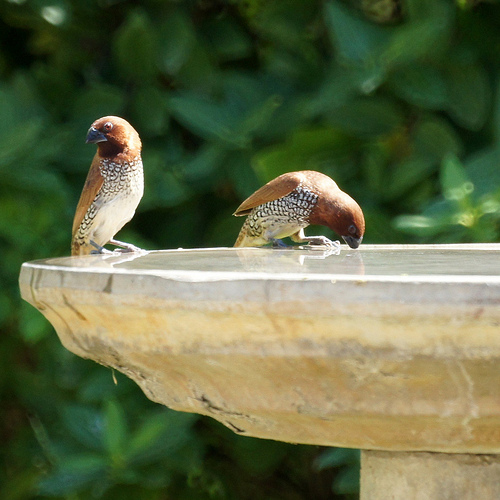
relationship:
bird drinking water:
[226, 168, 368, 253] [44, 244, 499, 278]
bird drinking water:
[70, 112, 144, 256] [44, 244, 499, 278]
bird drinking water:
[226, 168, 368, 253] [42, 245, 484, 281]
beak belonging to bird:
[79, 121, 111, 148] [56, 105, 155, 261]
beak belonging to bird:
[335, 231, 368, 255] [226, 168, 368, 253]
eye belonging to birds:
[100, 120, 112, 133] [74, 108, 156, 259]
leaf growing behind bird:
[168, 97, 252, 151] [226, 168, 368, 253]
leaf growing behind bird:
[155, 6, 193, 76] [226, 168, 368, 253]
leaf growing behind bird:
[237, 3, 328, 68] [226, 168, 368, 253]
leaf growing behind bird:
[110, 10, 163, 87] [70, 112, 144, 256]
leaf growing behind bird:
[66, 88, 124, 126] [70, 112, 144, 256]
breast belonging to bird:
[99, 165, 145, 236] [70, 112, 144, 256]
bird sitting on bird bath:
[41, 112, 162, 264] [25, 235, 499, 454]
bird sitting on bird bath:
[226, 168, 368, 253] [25, 235, 499, 454]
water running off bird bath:
[112, 245, 500, 275] [21, 237, 498, 492]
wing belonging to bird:
[188, 163, 355, 215] [226, 168, 368, 253]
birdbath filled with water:
[14, 240, 500, 452] [66, 245, 499, 277]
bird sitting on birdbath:
[70, 112, 144, 256] [14, 240, 500, 452]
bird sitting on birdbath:
[226, 168, 368, 253] [14, 240, 500, 452]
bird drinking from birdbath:
[226, 168, 368, 253] [14, 240, 500, 452]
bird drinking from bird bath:
[226, 168, 368, 253] [21, 237, 498, 492]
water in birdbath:
[112, 245, 500, 275] [213, 281, 488, 454]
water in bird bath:
[170, 245, 495, 275] [21, 237, 498, 492]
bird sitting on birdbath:
[70, 112, 144, 256] [15, 240, 499, 498]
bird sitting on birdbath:
[226, 168, 368, 253] [15, 240, 499, 498]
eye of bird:
[341, 221, 362, 236] [251, 157, 376, 246]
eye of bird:
[100, 120, 112, 133] [70, 112, 144, 256]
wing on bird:
[234, 167, 323, 215] [226, 168, 368, 253]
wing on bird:
[64, 158, 104, 240] [65, 110, 147, 264]